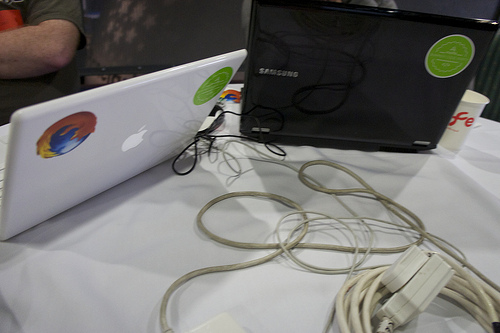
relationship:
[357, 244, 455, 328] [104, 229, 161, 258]
cord on top of table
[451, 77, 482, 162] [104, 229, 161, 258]
coffee cup on table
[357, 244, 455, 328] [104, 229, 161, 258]
cord on table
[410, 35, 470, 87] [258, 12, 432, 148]
sticker on computer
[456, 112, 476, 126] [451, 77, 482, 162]
letters on coffee cup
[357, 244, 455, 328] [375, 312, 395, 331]
cord with outlet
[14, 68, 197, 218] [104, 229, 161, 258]
laptop on table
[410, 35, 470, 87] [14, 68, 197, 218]
sticker on laptop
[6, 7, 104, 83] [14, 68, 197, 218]
man in front of laptop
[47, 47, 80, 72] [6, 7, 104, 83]
elbow of man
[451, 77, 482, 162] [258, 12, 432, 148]
coffee cup next to computer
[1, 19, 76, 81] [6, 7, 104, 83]
arm of man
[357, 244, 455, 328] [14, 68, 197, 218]
cord next to laptop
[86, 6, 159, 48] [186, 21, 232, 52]
lights on wall